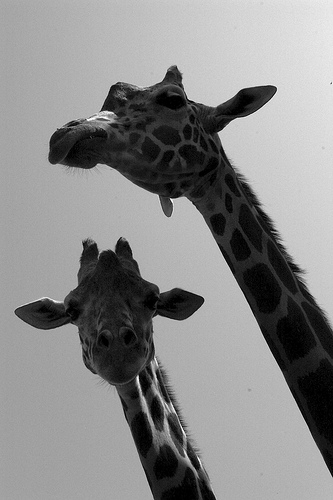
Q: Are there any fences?
A: No, there are no fences.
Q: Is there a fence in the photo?
A: No, there are no fences.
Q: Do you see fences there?
A: No, there are no fences.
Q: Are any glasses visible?
A: No, there are no glasses.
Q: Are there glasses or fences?
A: No, there are no glasses or fences.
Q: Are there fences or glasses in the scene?
A: No, there are no glasses or fences.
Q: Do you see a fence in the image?
A: No, there are no fences.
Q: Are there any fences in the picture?
A: No, there are no fences.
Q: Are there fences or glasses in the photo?
A: No, there are no fences or glasses.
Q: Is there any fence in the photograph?
A: No, there are no fences.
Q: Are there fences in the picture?
A: No, there are no fences.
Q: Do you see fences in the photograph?
A: No, there are no fences.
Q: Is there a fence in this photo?
A: No, there are no fences.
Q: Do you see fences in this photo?
A: No, there are no fences.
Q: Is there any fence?
A: No, there are no fences.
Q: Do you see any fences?
A: No, there are no fences.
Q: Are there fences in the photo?
A: No, there are no fences.